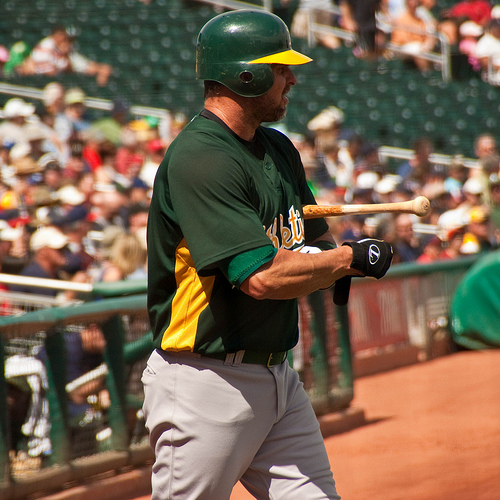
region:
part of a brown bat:
[295, 195, 432, 217]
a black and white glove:
[338, 236, 393, 276]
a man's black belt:
[209, 342, 292, 369]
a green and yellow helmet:
[192, 8, 314, 103]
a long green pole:
[389, 260, 471, 276]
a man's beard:
[260, 100, 287, 125]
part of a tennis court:
[323, 349, 498, 497]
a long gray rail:
[302, 8, 453, 77]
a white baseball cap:
[32, 228, 69, 253]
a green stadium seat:
[388, 88, 416, 113]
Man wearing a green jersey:
[124, 8, 394, 498]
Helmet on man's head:
[183, 5, 315, 102]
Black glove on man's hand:
[336, 228, 394, 282]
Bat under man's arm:
[287, 182, 432, 238]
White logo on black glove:
[363, 243, 385, 268]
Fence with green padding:
[3, 265, 381, 497]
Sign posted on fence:
[292, 261, 499, 385]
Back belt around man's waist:
[163, 330, 293, 374]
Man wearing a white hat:
[6, 230, 76, 309]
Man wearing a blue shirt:
[384, 216, 422, 264]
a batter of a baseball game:
[141, 14, 432, 499]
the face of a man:
[271, 59, 299, 124]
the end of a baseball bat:
[317, 188, 445, 218]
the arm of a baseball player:
[166, 228, 397, 316]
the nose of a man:
[283, 68, 302, 88]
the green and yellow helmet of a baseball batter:
[188, 4, 317, 84]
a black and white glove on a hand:
[339, 235, 396, 281]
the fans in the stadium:
[16, 123, 134, 258]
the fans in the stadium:
[328, 135, 449, 235]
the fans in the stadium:
[349, 6, 484, 59]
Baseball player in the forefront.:
[112, 8, 433, 493]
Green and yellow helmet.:
[191, 8, 313, 105]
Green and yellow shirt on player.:
[150, 8, 331, 360]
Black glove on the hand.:
[339, 233, 396, 282]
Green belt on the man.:
[135, 5, 325, 372]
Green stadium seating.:
[2, 1, 498, 153]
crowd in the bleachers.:
[1, 86, 498, 295]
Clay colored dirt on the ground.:
[115, 338, 499, 498]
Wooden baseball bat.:
[302, 190, 437, 233]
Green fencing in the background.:
[0, 274, 358, 486]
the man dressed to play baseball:
[140, 9, 428, 499]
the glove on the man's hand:
[340, 237, 393, 280]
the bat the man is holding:
[301, 195, 429, 219]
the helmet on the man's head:
[194, 9, 311, 97]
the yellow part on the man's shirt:
[160, 233, 215, 355]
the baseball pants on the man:
[142, 347, 339, 498]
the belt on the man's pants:
[202, 349, 289, 368]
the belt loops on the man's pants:
[223, 349, 243, 367]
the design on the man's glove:
[366, 242, 381, 264]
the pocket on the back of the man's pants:
[142, 362, 155, 377]